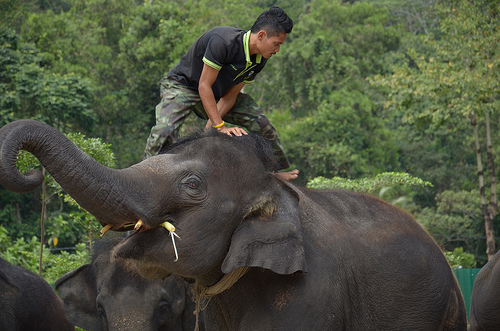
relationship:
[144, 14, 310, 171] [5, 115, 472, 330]
man riding elephant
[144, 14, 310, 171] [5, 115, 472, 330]
man touching elephant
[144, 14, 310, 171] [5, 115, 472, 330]
man on elephant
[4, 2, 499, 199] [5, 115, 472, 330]
trees are behind elephant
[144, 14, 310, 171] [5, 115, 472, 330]
man on top of elephant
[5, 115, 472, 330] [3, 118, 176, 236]
elephant has trunk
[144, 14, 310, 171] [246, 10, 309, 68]
man has a head